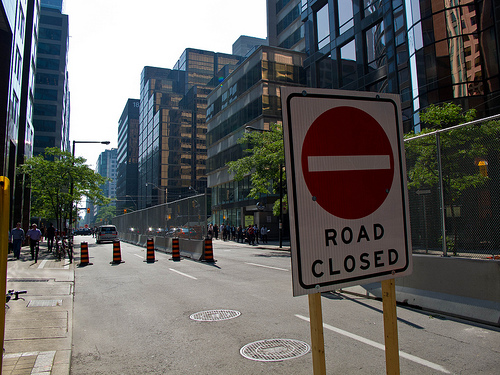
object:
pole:
[381, 273, 402, 374]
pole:
[310, 293, 329, 373]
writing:
[312, 222, 399, 280]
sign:
[277, 82, 416, 298]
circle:
[299, 104, 397, 220]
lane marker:
[167, 265, 198, 281]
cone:
[79, 240, 89, 265]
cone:
[109, 238, 125, 265]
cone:
[144, 233, 158, 262]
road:
[68, 233, 500, 375]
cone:
[171, 233, 181, 262]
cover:
[189, 308, 237, 324]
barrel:
[197, 233, 221, 263]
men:
[6, 218, 26, 261]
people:
[255, 223, 271, 239]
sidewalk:
[176, 222, 499, 264]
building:
[137, 34, 265, 231]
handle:
[5, 289, 26, 302]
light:
[100, 140, 110, 145]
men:
[24, 220, 43, 260]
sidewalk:
[4, 237, 74, 375]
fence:
[110, 189, 215, 262]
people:
[214, 219, 231, 246]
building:
[202, 39, 320, 251]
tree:
[15, 138, 116, 258]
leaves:
[51, 163, 58, 170]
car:
[94, 220, 122, 244]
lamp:
[62, 139, 111, 240]